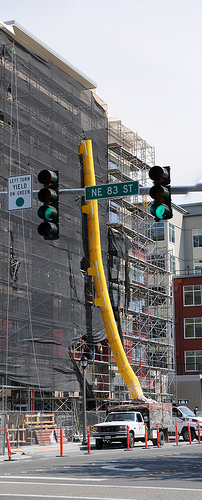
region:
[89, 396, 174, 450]
truck parked on a street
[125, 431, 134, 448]
front wheel on a truck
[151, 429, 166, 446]
rear wheel on a truck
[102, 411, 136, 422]
front windshield on a truck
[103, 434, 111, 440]
front licence plate on a truck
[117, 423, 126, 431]
front headlight on a truck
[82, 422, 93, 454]
orange traffic post on a street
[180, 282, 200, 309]
windows on a building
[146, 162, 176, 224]
traffic signal on a pole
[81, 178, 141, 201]
street sign on a pole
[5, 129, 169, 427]
building under construction across street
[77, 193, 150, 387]
yellow tube near building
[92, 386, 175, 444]
white truck on street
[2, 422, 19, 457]
orange barrier on road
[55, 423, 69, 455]
orange barrier on road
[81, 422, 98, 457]
orange barrier on road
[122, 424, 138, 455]
orange barrier on road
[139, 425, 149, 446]
orange barrier on road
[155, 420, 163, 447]
orange barrier on road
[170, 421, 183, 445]
orange barrier on road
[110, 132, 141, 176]
scaffolding on a building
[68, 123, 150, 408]
construction site garbage chute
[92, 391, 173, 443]
a truck with garbage in the back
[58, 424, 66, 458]
an orange construction pole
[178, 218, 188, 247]
the white exterior of a building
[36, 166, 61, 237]
a traffic light on a pole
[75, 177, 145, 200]
a street sign on a pole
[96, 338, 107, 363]
a person standing on scaffolding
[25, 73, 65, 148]
black mesh covering scaffolding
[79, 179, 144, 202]
green and white street sign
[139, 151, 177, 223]
traffic lights with the green light on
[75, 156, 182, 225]
street sign and a traffic light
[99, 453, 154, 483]
arrow on the road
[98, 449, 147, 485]
white arrow on the road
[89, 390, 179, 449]
truck parked on the street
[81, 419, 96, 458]
orange and white construction poles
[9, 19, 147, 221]
building under construction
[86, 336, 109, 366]
men working on a building under construction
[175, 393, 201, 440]
the front of a white truck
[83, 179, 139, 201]
green and white rectangular street sign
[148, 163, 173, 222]
black metal traffic light above street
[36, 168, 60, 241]
black metal traffic light above street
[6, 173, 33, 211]
black white and green traffic sign above street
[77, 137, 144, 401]
large tubular yellow chute going into truck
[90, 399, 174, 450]
white dump truck parked on side of street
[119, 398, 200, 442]
white truck parked on side of street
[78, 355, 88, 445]
gray and black metal light post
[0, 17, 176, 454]
large building covered with scaffolding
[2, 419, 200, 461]
row of orange construction markers